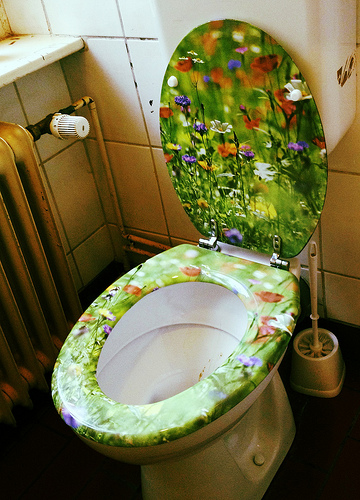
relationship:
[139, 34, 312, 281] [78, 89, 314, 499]
garden on toilet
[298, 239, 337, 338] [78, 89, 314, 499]
brush near toilet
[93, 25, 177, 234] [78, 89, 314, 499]
tile behind toilet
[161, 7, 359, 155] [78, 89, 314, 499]
tank near toilet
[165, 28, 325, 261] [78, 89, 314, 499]
lid on toilet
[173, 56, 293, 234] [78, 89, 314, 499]
flowers on toilet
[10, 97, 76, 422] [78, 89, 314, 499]
radiator near toilet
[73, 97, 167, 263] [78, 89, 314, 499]
pipes near toilet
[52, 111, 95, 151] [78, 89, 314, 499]
vent near toilet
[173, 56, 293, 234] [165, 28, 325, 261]
flowers on lid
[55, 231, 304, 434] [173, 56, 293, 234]
seat has flowers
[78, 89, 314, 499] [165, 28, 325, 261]
toilet has lid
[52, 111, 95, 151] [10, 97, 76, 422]
vent near radiator